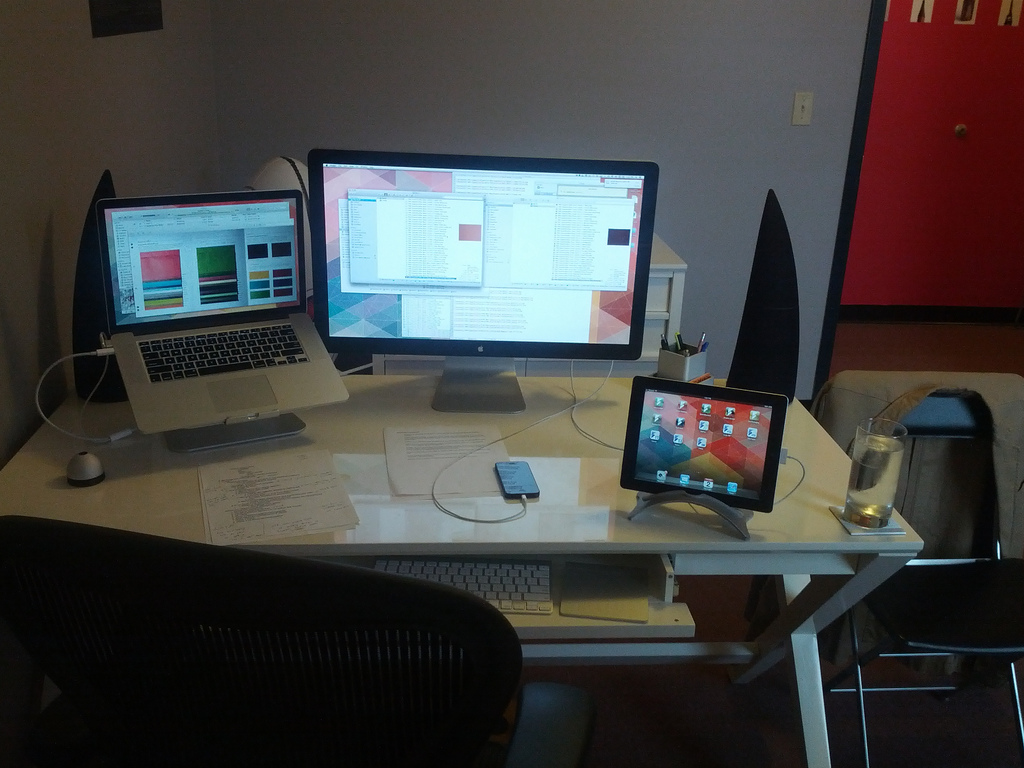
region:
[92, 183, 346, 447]
Laptop on desk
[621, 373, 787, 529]
Tablet in stand on desk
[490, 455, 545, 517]
Phone being charged on desk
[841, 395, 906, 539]
Filled glass on table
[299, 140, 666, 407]
Computer monitor on desk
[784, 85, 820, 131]
Light switch on wall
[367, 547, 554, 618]
Keyboard on desk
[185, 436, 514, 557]
Collection of papers on desk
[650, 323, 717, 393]
Container holding pens and pencils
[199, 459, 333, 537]
paper on the desk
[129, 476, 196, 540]
the desk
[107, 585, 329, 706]
a black chair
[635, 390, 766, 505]
a tablet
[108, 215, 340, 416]
a laptop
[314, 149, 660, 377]
a computer monitor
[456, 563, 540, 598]
a keyboard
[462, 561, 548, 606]
the keyboard is white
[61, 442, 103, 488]
Gray mouse next to the laptop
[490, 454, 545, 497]
iPhone in front of the monitor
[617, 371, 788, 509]
iPad next to the iPhone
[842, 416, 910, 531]
Glass of water next to the iPad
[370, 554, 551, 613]
White keyboard on the desk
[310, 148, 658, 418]
Large monitor next to a laptop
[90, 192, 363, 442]
Laptop is propped up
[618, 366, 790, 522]
iPad is sitting on a stand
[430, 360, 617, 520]
White cable plugged into an iPhone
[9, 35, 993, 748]
Computer monitors on table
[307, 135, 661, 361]
A large computer monitor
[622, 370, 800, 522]
A small black I-pad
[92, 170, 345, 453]
A small beige laptop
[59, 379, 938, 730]
A beige table with metal legs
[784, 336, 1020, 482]
A beige jacket on back of chair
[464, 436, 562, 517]
A cell phone charging on table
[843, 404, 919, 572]
A clear glass of drink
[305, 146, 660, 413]
large computer monitor on the desk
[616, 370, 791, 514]
tablet computer on the desk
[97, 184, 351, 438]
laptop computer on the dest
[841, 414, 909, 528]
a glass of water on a coaster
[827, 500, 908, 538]
coaster on the corner of the desk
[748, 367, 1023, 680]
gray jacket hanging on a chair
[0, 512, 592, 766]
chair in front of the desk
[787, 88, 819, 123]
light switch on the wall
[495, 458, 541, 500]
smartphone on top of the desk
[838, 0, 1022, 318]
red door in the corner